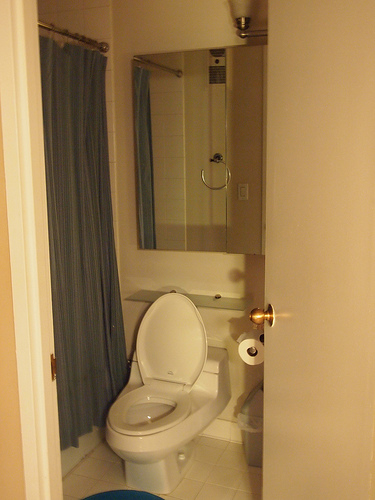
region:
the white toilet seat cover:
[108, 385, 190, 431]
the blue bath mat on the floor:
[84, 491, 157, 499]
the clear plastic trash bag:
[236, 386, 263, 432]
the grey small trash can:
[237, 409, 257, 463]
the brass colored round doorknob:
[249, 303, 273, 322]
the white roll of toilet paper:
[237, 326, 260, 358]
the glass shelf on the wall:
[125, 286, 256, 314]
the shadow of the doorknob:
[228, 265, 247, 279]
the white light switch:
[237, 179, 249, 198]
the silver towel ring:
[199, 149, 229, 187]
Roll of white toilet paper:
[232, 327, 275, 370]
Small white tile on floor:
[208, 460, 249, 494]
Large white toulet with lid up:
[102, 304, 241, 481]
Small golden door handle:
[246, 285, 284, 340]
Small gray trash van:
[236, 372, 278, 492]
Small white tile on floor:
[66, 441, 114, 479]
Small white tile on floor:
[58, 470, 106, 485]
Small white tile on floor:
[194, 436, 233, 465]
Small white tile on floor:
[236, 468, 256, 496]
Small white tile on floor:
[191, 482, 246, 498]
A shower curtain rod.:
[35, 18, 111, 52]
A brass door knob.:
[246, 301, 275, 327]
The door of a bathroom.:
[248, 0, 373, 499]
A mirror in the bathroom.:
[131, 41, 268, 255]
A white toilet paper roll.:
[235, 324, 265, 365]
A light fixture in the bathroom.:
[226, 0, 268, 41]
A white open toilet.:
[100, 290, 233, 495]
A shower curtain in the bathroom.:
[36, 32, 129, 450]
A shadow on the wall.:
[225, 255, 265, 426]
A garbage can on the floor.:
[233, 375, 263, 469]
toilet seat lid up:
[135, 291, 210, 387]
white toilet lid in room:
[139, 293, 203, 383]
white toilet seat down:
[109, 390, 186, 435]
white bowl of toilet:
[131, 393, 165, 425]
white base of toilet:
[99, 435, 193, 490]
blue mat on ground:
[80, 488, 161, 499]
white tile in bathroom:
[201, 445, 244, 492]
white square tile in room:
[204, 456, 238, 488]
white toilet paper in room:
[229, 331, 267, 363]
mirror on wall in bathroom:
[124, 47, 230, 254]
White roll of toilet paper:
[225, 309, 268, 367]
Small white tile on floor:
[201, 459, 233, 489]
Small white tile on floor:
[58, 473, 99, 497]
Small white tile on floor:
[169, 469, 208, 494]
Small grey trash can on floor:
[236, 377, 269, 487]